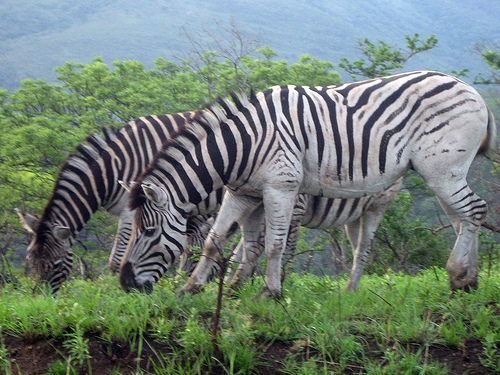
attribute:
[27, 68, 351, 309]
zebra — striped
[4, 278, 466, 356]
roots — growing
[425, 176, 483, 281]
leg — lifted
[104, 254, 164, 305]
nose — black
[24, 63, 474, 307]
zebras — eating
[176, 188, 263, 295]
front leg — white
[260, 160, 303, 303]
front leg — white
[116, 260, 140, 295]
snout — black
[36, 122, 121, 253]
mane — black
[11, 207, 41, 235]
ear — black, white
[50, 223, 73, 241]
ear — black, white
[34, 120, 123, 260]
mane — white, black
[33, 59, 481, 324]
zebra — three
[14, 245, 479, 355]
weeds — tall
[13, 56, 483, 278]
trees — light green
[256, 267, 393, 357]
grass — green